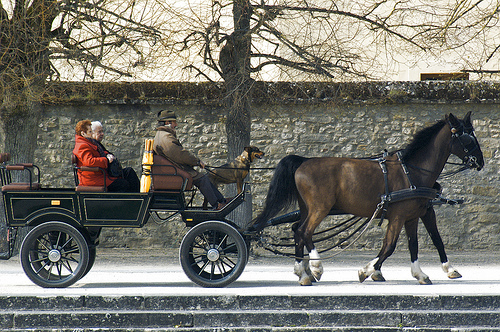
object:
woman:
[72, 118, 140, 194]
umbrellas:
[138, 138, 154, 193]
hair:
[89, 120, 103, 133]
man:
[90, 120, 124, 171]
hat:
[156, 109, 178, 123]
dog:
[201, 146, 265, 210]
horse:
[246, 110, 488, 285]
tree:
[168, 0, 500, 238]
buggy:
[0, 154, 258, 289]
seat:
[1, 154, 45, 192]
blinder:
[453, 128, 480, 143]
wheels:
[178, 219, 252, 287]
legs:
[302, 210, 329, 268]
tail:
[243, 154, 310, 234]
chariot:
[140, 136, 251, 288]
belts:
[205, 165, 278, 170]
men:
[151, 105, 236, 209]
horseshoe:
[370, 273, 386, 282]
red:
[80, 174, 95, 184]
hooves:
[298, 274, 314, 288]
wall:
[31, 79, 500, 254]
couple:
[71, 118, 142, 193]